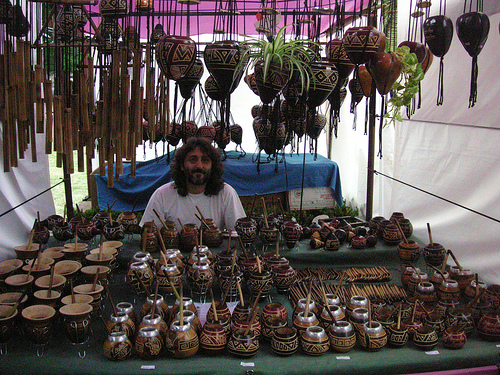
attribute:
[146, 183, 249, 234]
shirt — white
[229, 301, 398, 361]
bowls — curved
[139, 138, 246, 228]
man — light skinned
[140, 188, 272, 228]
tshirt — white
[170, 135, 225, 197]
hair — long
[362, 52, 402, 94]
red pot — hanging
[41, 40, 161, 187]
chimes — bamboo, hanging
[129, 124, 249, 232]
man — curly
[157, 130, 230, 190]
curly hair — long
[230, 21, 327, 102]
fern — green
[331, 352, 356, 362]
sticker — white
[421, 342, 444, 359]
sticker — white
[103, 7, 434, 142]
wind chimes — hanging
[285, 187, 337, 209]
box — white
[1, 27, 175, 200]
bells — wood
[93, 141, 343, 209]
tarp — blue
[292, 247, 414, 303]
smashers — wood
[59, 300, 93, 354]
goblet — fancy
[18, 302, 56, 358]
goblet — fancy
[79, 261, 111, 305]
goblet — fancy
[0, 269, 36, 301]
goblet — fancy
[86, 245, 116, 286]
goblet — fancy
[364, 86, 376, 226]
pole — wooden